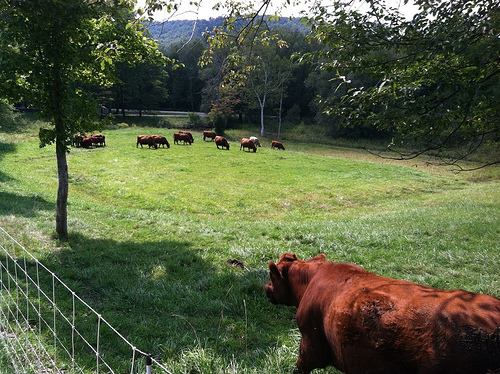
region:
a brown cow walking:
[251, 242, 498, 362]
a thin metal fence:
[0, 235, 130, 362]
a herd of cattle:
[48, 122, 296, 170]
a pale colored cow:
[244, 130, 271, 152]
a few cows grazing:
[136, 124, 291, 162]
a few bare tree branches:
[351, 143, 492, 183]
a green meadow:
[94, 115, 475, 255]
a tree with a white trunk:
[217, 35, 290, 140]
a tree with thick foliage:
[12, 0, 145, 236]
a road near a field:
[91, 91, 333, 205]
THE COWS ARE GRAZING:
[62, 120, 288, 155]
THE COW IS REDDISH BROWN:
[243, 247, 498, 372]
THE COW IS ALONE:
[255, 237, 499, 371]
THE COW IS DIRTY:
[262, 242, 497, 372]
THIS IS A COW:
[253, 241, 499, 371]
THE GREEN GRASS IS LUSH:
[3, 112, 498, 369]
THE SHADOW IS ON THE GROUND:
[0, 225, 302, 372]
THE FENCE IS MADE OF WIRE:
[3, 225, 173, 372]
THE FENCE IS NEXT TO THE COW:
[3, 225, 176, 372]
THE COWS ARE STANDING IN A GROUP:
[68, 122, 291, 159]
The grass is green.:
[223, 192, 375, 214]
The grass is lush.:
[295, 153, 429, 254]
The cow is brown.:
[242, 241, 476, 371]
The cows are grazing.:
[20, 109, 331, 179]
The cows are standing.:
[19, 116, 319, 166]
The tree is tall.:
[23, 2, 100, 127]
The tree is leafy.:
[12, 1, 119, 152]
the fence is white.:
[20, 256, 100, 366]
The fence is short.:
[5, 246, 53, 363]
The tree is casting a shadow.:
[47, 218, 274, 370]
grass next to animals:
[160, 168, 228, 220]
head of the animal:
[243, 240, 315, 311]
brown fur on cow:
[226, 237, 404, 338]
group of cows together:
[88, 100, 269, 185]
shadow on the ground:
[153, 228, 239, 308]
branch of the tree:
[38, 139, 98, 222]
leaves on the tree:
[393, 75, 447, 117]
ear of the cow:
[261, 253, 281, 288]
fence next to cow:
[1, 263, 109, 354]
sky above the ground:
[196, 2, 218, 19]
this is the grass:
[178, 163, 275, 200]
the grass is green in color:
[170, 192, 302, 217]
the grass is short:
[166, 163, 261, 218]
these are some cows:
[71, 127, 281, 159]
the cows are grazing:
[133, 122, 285, 158]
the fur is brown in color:
[315, 279, 365, 344]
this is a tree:
[8, 3, 134, 251]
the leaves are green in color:
[91, 17, 125, 62]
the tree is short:
[12, 9, 137, 255]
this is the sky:
[200, 2, 210, 19]